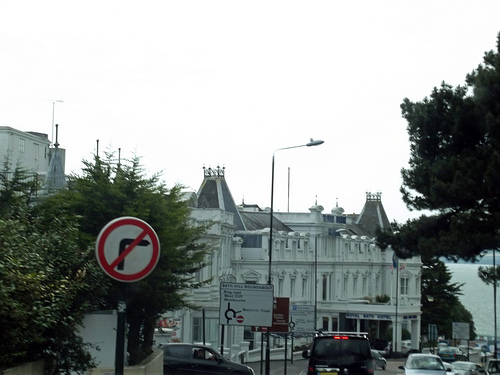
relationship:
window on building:
[338, 271, 354, 297] [143, 156, 440, 361]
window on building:
[351, 276, 359, 294] [150, 164, 422, 365]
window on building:
[398, 275, 405, 295] [173, 165, 422, 360]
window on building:
[284, 237, 290, 252] [2, 164, 424, 361]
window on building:
[295, 236, 301, 248] [230, 210, 320, 360]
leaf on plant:
[16, 223, 23, 230] [1, 151, 101, 373]